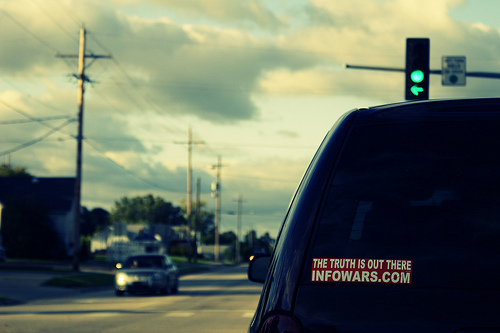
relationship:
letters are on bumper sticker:
[313, 259, 413, 284] [310, 251, 418, 292]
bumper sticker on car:
[310, 251, 418, 292] [245, 93, 499, 332]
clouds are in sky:
[4, 4, 478, 125] [1, 4, 499, 207]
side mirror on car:
[239, 249, 275, 284] [245, 93, 499, 332]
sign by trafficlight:
[440, 50, 470, 87] [406, 37, 429, 101]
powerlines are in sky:
[10, 2, 245, 221] [1, 4, 499, 207]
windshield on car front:
[123, 252, 174, 271] [110, 245, 180, 295]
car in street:
[245, 93, 499, 332] [0, 256, 270, 332]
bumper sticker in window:
[310, 251, 418, 292] [297, 103, 499, 298]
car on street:
[245, 93, 499, 332] [0, 256, 270, 332]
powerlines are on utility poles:
[10, 2, 245, 221] [63, 30, 277, 263]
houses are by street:
[13, 169, 228, 267] [0, 256, 270, 332]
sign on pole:
[440, 50, 470, 87] [340, 60, 497, 88]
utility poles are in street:
[63, 30, 277, 263] [0, 256, 270, 332]